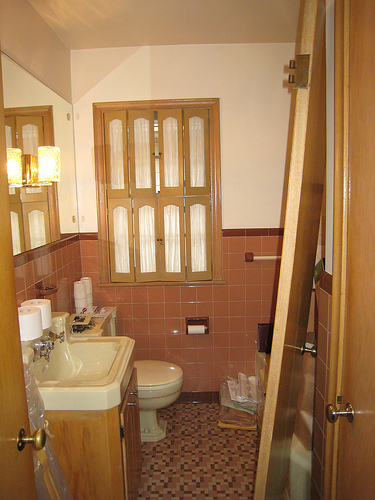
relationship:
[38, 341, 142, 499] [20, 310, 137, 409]
cabinet under sink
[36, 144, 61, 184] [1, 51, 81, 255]
light mounted on mirror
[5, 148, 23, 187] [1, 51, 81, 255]
light mounted on mirror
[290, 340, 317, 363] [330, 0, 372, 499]
knob on door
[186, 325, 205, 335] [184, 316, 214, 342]
toilet paper on holder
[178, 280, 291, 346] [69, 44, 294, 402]
tiles on wall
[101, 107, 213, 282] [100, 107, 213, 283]
paneled shutters on window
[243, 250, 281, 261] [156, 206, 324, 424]
rod on wall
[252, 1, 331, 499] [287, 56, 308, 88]
door off hinges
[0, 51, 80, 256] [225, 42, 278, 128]
mirror on wall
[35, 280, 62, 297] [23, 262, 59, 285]
soap dish on wall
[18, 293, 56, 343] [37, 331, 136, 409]
rolls sitting on sink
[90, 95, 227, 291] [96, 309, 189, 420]
cabinet over toilet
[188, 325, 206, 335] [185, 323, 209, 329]
toilet paper on holder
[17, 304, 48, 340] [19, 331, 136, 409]
toilet roll on sink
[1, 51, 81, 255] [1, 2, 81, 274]
mirror on wall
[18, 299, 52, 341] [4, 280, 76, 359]
rolls of toilet paper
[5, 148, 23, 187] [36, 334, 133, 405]
light over sink